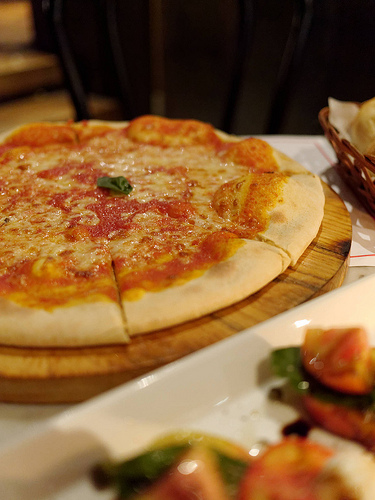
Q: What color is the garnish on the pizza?
A: Green.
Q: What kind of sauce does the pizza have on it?
A: Tomato.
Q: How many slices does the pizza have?
A: Eight.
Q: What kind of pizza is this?
A: Cheese.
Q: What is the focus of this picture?
A: Pizza.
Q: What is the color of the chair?
A: Black.